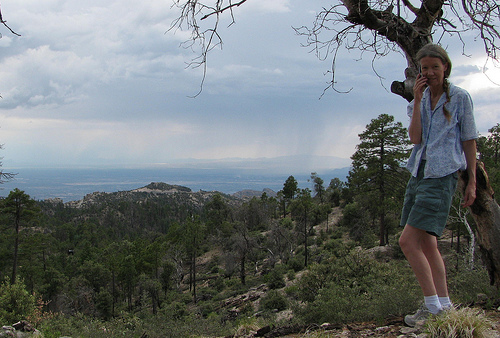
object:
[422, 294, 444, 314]
sock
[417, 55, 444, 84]
face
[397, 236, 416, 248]
bent knee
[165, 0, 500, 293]
tree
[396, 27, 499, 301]
trunk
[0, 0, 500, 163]
sky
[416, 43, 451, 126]
hair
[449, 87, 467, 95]
shoulder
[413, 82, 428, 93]
fingers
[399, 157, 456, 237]
shorts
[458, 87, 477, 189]
arm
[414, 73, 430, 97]
hand holding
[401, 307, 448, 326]
grey shoes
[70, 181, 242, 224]
hill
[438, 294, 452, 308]
white sock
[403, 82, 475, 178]
blue shirt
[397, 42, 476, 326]
woman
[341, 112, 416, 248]
trees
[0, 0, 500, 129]
cloud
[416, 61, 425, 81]
cell phone